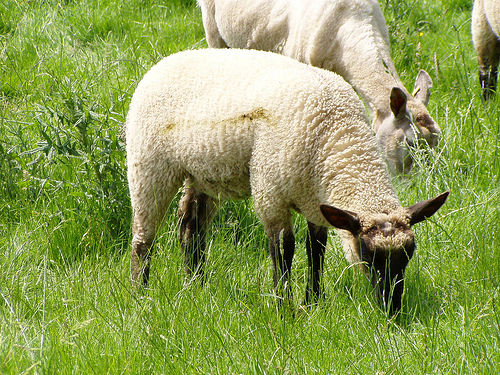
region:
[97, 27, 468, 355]
the sheep is grazing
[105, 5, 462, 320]
these are two sheep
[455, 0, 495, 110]
a hind leg of a sheep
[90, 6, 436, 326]
the sheep are grazing in the grass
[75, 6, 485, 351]
the sheep are eating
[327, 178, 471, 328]
the sheep has a black face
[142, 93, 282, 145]
its wool has a stain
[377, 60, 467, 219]
the grass is covering the sheep's head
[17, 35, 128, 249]
a tall green plant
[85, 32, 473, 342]
sheep in a grass field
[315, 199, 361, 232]
black colored ear on sheep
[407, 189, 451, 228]
black colored ear on sheep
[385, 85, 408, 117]
black colored ear on sheep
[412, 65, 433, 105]
black colored ear on sheep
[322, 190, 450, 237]
black colored ears on sheep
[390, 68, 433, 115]
black colored ears on sheep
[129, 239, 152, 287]
black colored leg on sheep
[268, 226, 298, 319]
black colored leg on sheep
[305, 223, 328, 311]
black colored leg on sheep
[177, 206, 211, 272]
black colored leg on sheep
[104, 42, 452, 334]
A sheep eating tall grass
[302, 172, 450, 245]
sheep's ears pointing outwards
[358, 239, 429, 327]
sheep's face is black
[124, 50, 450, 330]
the sheep is white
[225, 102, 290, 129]
brown stain on the sheep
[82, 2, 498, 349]
multiple sheep in the grass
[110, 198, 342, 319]
sheep's legs are black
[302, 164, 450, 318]
sheep's head is down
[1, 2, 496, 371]
sun shining on sheep and grass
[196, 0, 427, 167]
the sheep has no fur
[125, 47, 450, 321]
A dirty white sheep.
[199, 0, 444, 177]
A white sheep grazing.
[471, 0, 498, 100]
Rear pair of sheep legs.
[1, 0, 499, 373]
A bright green pasture.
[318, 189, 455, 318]
Brown and white sheeps head.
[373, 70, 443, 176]
A white sheeps head.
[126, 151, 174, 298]
Brown and white sheep leg.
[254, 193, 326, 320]
Front pair of legs.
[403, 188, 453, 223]
Dark brown sheeps ear.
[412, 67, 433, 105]
Light colored sheeps ear.